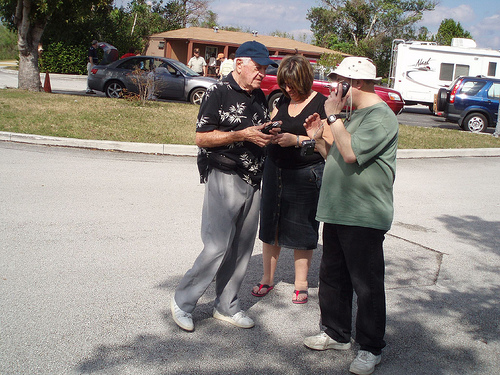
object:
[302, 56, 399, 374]
man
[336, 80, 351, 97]
cellphone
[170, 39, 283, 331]
man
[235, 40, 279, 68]
hat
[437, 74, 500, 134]
suv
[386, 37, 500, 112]
rv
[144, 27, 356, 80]
building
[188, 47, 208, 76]
people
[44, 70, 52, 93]
cone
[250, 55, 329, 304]
woman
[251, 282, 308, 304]
sandals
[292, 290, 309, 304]
feet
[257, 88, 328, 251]
dress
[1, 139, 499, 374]
pavement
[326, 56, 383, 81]
hat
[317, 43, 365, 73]
tree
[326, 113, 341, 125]
watch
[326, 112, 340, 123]
wrist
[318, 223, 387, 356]
pants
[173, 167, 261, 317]
pants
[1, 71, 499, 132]
pavement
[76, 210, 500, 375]
shadow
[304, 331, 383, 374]
shoes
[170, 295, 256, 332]
shoes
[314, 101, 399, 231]
shirt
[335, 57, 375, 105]
head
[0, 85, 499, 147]
grass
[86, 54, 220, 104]
car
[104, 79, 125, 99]
tire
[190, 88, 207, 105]
tire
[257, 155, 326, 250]
skirt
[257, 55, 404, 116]
cars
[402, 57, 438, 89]
logo